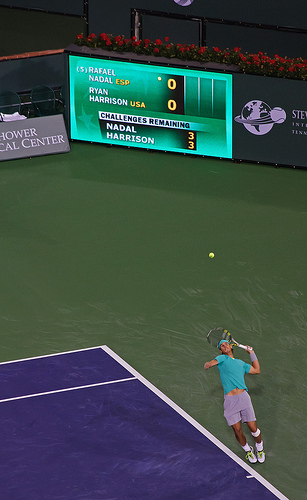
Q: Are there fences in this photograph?
A: No, there are no fences.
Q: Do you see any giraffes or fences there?
A: No, there are no fences or giraffes.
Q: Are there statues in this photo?
A: No, there are no statues.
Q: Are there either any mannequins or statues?
A: No, there are no statues or mannequins.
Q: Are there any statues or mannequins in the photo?
A: No, there are no statues or mannequins.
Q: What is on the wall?
A: The flowers are on the wall.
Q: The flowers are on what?
A: The flowers are on the wall.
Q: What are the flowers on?
A: The flowers are on the wall.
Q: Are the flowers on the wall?
A: Yes, the flowers are on the wall.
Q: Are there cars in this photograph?
A: No, there are no cars.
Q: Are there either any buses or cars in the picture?
A: No, there are no cars or buses.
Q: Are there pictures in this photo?
A: No, there are no pictures.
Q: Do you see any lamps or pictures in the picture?
A: No, there are no pictures or lamps.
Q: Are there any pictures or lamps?
A: No, there are no pictures or lamps.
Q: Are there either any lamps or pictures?
A: No, there are no pictures or lamps.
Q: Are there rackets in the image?
A: Yes, there is a racket.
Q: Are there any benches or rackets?
A: Yes, there is a racket.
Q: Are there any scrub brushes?
A: No, there are no scrub brushes.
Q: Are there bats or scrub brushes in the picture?
A: No, there are no scrub brushes or bats.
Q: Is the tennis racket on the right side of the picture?
A: Yes, the tennis racket is on the right of the image.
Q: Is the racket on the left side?
A: No, the racket is on the right of the image.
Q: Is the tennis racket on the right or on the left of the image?
A: The tennis racket is on the right of the image.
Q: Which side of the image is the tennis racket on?
A: The tennis racket is on the right of the image.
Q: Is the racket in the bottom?
A: Yes, the racket is in the bottom of the image.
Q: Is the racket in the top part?
A: No, the racket is in the bottom of the image.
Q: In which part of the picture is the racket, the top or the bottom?
A: The racket is in the bottom of the image.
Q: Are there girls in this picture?
A: No, there are no girls.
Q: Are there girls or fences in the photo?
A: No, there are no girls or fences.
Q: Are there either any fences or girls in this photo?
A: No, there are no girls or fences.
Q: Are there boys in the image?
A: No, there are no boys.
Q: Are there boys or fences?
A: No, there are no boys or fences.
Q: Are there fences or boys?
A: No, there are no boys or fences.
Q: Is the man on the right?
A: Yes, the man is on the right of the image.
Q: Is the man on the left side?
A: No, the man is on the right of the image.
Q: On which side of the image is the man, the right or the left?
A: The man is on the right of the image.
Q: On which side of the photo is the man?
A: The man is on the right of the image.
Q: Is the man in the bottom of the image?
A: Yes, the man is in the bottom of the image.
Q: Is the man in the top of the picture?
A: No, the man is in the bottom of the image.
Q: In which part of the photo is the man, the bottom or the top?
A: The man is in the bottom of the image.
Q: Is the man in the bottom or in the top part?
A: The man is in the bottom of the image.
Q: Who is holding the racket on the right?
A: The man is holding the tennis racket.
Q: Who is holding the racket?
A: The man is holding the tennis racket.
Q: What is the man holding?
A: The man is holding the tennis racket.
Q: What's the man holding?
A: The man is holding the tennis racket.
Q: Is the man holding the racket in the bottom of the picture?
A: Yes, the man is holding the tennis racket.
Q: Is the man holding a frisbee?
A: No, the man is holding the tennis racket.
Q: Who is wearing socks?
A: The man is wearing socks.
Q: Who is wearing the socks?
A: The man is wearing socks.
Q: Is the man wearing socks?
A: Yes, the man is wearing socks.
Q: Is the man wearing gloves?
A: No, the man is wearing socks.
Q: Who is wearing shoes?
A: The man is wearing shoes.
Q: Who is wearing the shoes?
A: The man is wearing shoes.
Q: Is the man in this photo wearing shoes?
A: Yes, the man is wearing shoes.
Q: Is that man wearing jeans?
A: No, the man is wearing shoes.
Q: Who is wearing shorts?
A: The man is wearing shorts.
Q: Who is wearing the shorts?
A: The man is wearing shorts.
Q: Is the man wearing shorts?
A: Yes, the man is wearing shorts.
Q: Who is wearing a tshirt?
A: The man is wearing a tshirt.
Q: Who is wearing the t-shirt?
A: The man is wearing a tshirt.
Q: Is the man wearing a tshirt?
A: Yes, the man is wearing a tshirt.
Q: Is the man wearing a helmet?
A: No, the man is wearing a tshirt.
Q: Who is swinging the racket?
A: The man is swinging the racket.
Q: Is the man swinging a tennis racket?
A: Yes, the man is swinging a tennis racket.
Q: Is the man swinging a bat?
A: No, the man is swinging a tennis racket.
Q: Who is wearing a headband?
A: The man is wearing a headband.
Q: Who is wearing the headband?
A: The man is wearing a headband.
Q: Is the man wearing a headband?
A: Yes, the man is wearing a headband.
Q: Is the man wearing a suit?
A: No, the man is wearing a headband.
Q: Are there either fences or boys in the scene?
A: No, there are no boys or fences.